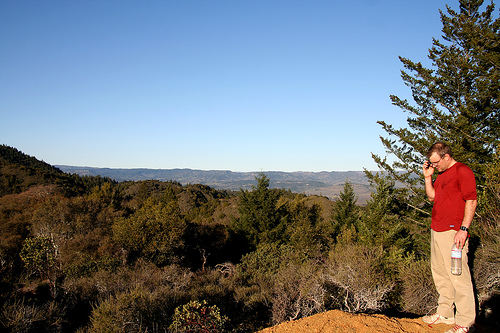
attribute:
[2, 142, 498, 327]
landscape — mountainous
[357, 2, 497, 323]
pine tree — big, tall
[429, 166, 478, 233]
t-shirt — red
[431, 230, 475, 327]
pants — brown, tan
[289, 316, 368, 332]
soil — brown, mounded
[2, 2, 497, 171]
sky — blue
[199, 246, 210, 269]
branches — pointed